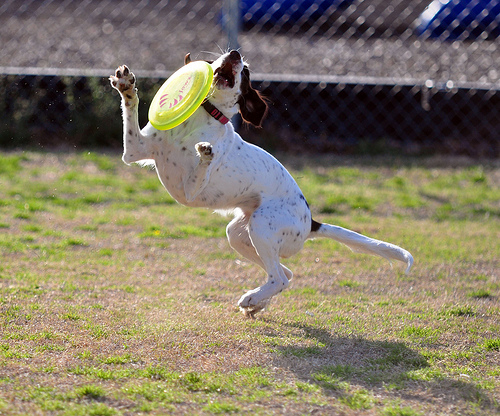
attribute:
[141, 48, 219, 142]
frisbee — yellow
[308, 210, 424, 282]
tail — white, black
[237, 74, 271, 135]
ear — black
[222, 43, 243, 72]
nose — black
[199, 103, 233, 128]
collar — red, black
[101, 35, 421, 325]
dog — white, black, jumping, White, spotted, dark, white spotted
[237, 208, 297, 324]
leg — white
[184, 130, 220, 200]
leg — white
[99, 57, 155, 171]
leg — white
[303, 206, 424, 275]
tail — white dog's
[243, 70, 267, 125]
ear — white dog's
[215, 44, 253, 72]
nose — white dog's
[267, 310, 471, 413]
shadow — white dog's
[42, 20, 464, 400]
day — sunny 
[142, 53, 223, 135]
frisbee — yellow  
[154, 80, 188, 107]
pattern — red 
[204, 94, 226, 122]
collar — Red dog 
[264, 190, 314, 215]
spots — black  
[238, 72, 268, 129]
ear — Dog's brown left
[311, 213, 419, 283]
tail — brown patch, White dog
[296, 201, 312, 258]
region — Dog's hind 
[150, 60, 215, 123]
frisbee — Yellow 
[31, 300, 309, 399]
grass — green , dead patches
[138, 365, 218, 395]
grass — Dog 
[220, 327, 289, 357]
ground — off 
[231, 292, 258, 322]
paw — Dog , off 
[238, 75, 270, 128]
ear — Brown, floppy dog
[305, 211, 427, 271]
tail — White dog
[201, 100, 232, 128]
collar — Red 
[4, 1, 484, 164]
fence — Blurry chainlink , Wire 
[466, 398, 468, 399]
field — grassy 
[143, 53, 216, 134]
frisbee — dog toy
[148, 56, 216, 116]
frisbee — neon yellow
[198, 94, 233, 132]
collar — red, black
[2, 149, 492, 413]
grass — patchy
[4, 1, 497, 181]
fence — chain-link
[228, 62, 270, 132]
ears — brown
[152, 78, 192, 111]
design — red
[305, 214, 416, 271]
tail — white